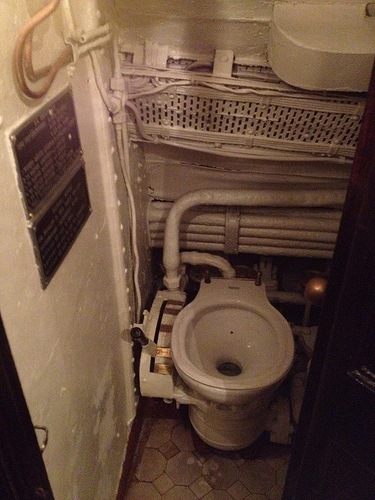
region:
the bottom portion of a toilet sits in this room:
[171, 270, 303, 454]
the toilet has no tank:
[201, 258, 264, 297]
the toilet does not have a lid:
[171, 296, 287, 393]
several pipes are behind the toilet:
[151, 174, 324, 283]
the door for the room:
[279, 113, 371, 496]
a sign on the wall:
[2, 82, 113, 282]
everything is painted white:
[72, 6, 324, 253]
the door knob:
[301, 266, 322, 302]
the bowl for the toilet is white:
[177, 275, 287, 459]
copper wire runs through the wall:
[9, 6, 78, 104]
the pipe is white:
[130, 164, 205, 290]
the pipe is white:
[154, 179, 194, 291]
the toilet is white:
[174, 264, 311, 433]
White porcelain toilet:
[163, 267, 300, 453]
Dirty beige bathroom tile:
[128, 411, 290, 495]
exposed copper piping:
[5, 0, 77, 100]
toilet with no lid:
[166, 264, 296, 455]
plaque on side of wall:
[6, 81, 108, 292]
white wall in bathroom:
[1, 0, 165, 482]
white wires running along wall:
[104, 34, 343, 330]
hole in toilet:
[212, 348, 246, 378]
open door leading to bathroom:
[273, 108, 371, 496]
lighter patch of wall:
[85, 350, 127, 471]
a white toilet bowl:
[173, 269, 298, 450]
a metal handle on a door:
[35, 422, 52, 451]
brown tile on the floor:
[131, 451, 206, 495]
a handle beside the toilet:
[124, 310, 161, 363]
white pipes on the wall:
[147, 167, 342, 277]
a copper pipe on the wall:
[9, 7, 75, 103]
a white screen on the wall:
[142, 105, 356, 147]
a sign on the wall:
[0, 85, 98, 296]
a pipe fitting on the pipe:
[110, 74, 127, 95]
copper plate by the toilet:
[158, 298, 181, 375]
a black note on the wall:
[0, 87, 126, 280]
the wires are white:
[116, 136, 146, 328]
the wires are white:
[108, 124, 163, 334]